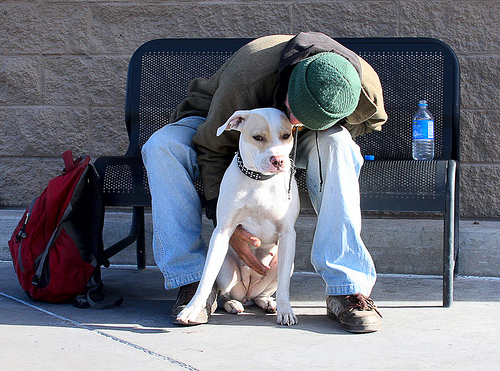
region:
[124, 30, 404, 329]
a man and a dog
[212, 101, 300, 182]
the head of a dog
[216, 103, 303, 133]
the ears of a dog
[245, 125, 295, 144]
the eye of a dog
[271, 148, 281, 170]
the nose of a dog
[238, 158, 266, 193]
the collar of a dog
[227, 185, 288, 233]
the chest of a dog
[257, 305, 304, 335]
the left paw of a dog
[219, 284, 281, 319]
the hind legs of a dog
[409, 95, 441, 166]
water bottle on a bench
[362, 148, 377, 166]
blue top to a water bottle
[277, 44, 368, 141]
man wearing a green hat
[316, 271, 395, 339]
man wearing a brown shoe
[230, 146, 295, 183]
dog wearing a black collar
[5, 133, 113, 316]
red backpack leaning against a bench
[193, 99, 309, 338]
man petting a dog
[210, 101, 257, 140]
right ear of a man's dog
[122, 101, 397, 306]
man wearing faded pants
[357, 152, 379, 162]
A blue cap on the chair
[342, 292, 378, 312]
A brown lace of the shoe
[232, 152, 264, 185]
There are silver studs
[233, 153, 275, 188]
A black collar with studs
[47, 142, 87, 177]
A red handle of a backpack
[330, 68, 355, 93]
Top of the green bonnet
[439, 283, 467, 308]
Tip of the black steel chair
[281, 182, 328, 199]
Tip of the black lace of the hood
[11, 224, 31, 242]
A black zipper on the bag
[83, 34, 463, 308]
Bench on the sidewalk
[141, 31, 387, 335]
Man sitting on the bench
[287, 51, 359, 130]
Hat on the man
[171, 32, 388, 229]
Jacket on the man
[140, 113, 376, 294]
Jeans on the man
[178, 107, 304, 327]
Dog sitting in front of the bench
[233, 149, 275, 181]
Collar on the dog's neck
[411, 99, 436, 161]
Water bottle on the bench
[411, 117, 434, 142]
Label on the water bottle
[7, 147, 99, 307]
Backpack on the ground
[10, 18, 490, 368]
a person with a dog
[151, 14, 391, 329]
a person on a bench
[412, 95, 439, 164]
a bottle of water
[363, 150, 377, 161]
a cap for a bottle of water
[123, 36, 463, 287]
a black metal bench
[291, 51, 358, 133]
a man wearing a hat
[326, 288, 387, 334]
a shoe with laces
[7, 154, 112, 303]
a backpack leaning on a bench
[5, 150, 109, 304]
a red backpack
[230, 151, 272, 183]
a black collar on a dog